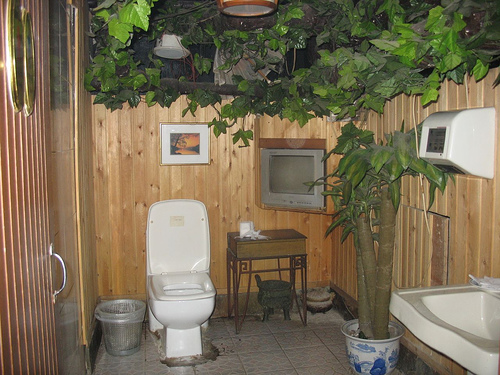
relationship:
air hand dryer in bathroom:
[422, 104, 491, 180] [38, 34, 500, 355]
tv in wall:
[256, 138, 332, 213] [239, 175, 253, 188]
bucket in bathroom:
[93, 299, 145, 356] [38, 34, 500, 355]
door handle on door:
[49, 242, 67, 304] [11, 166, 63, 213]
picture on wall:
[162, 126, 213, 161] [239, 175, 253, 188]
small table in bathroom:
[229, 229, 309, 310] [38, 34, 500, 355]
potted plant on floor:
[346, 297, 400, 365] [264, 341, 326, 367]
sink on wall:
[407, 292, 494, 358] [239, 175, 253, 188]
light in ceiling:
[216, 0, 287, 21] [88, 3, 96, 7]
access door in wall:
[401, 203, 454, 277] [239, 175, 253, 188]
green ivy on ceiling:
[345, 9, 400, 17] [88, 3, 96, 7]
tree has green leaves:
[346, 13, 472, 75] [124, 11, 147, 27]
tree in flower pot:
[346, 13, 472, 75] [343, 327, 402, 366]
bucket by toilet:
[93, 299, 145, 356] [145, 198, 217, 358]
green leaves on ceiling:
[124, 11, 147, 27] [88, 3, 96, 7]